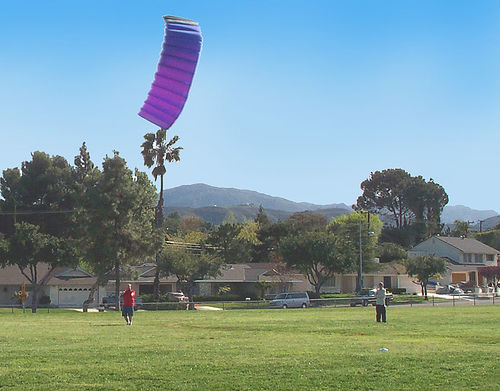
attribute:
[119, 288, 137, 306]
shirt — red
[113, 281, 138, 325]
man — walking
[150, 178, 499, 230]
mountain — majestic, in the distance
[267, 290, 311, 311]
van — grey, silver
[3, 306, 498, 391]
grass — green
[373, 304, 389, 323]
pants — black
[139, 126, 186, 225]
palm tree — green, tall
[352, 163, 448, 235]
tree — far away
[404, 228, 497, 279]
house — two story, white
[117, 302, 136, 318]
shorts — blue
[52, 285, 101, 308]
garage — white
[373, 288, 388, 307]
shirt — grey, white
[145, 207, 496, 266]
trees — far away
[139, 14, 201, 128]
kite — purple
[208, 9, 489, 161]
sky — clear, blue, cloudless